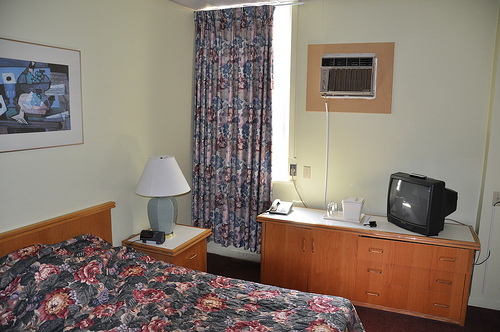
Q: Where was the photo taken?
A: It was taken at the hotel room.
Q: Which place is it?
A: It is a hotel room.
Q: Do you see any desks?
A: No, there are no desks.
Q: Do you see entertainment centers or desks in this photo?
A: No, there are no desks or entertainment centers.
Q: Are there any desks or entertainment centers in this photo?
A: No, there are no desks or entertainment centers.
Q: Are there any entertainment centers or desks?
A: No, there are no desks or entertainment centers.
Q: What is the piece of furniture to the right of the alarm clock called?
A: The piece of furniture is a dresser.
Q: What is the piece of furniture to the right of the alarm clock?
A: The piece of furniture is a dresser.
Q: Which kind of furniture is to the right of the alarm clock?
A: The piece of furniture is a dresser.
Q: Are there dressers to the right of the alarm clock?
A: Yes, there is a dresser to the right of the alarm clock.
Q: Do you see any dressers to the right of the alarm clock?
A: Yes, there is a dresser to the right of the alarm clock.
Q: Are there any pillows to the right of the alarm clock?
A: No, there is a dresser to the right of the alarm clock.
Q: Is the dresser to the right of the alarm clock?
A: Yes, the dresser is to the right of the alarm clock.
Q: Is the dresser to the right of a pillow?
A: No, the dresser is to the right of the alarm clock.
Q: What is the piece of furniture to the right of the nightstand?
A: The piece of furniture is a dresser.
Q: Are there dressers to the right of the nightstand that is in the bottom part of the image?
A: Yes, there is a dresser to the right of the nightstand.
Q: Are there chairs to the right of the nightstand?
A: No, there is a dresser to the right of the nightstand.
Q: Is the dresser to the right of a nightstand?
A: Yes, the dresser is to the right of a nightstand.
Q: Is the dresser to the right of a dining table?
A: No, the dresser is to the right of a nightstand.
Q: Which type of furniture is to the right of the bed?
A: The piece of furniture is a dresser.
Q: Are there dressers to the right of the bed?
A: Yes, there is a dresser to the right of the bed.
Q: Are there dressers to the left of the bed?
A: No, the dresser is to the right of the bed.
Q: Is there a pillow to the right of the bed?
A: No, there is a dresser to the right of the bed.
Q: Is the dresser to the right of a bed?
A: Yes, the dresser is to the right of a bed.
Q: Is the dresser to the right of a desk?
A: No, the dresser is to the right of a bed.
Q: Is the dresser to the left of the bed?
A: No, the dresser is to the right of the bed.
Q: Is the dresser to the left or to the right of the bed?
A: The dresser is to the right of the bed.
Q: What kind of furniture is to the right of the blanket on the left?
A: The piece of furniture is a dresser.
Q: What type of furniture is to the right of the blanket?
A: The piece of furniture is a dresser.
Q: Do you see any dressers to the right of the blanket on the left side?
A: Yes, there is a dresser to the right of the blanket.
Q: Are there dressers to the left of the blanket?
A: No, the dresser is to the right of the blanket.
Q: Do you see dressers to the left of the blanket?
A: No, the dresser is to the right of the blanket.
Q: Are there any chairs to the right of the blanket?
A: No, there is a dresser to the right of the blanket.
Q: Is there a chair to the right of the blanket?
A: No, there is a dresser to the right of the blanket.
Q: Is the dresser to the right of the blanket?
A: Yes, the dresser is to the right of the blanket.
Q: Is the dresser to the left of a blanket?
A: No, the dresser is to the right of a blanket.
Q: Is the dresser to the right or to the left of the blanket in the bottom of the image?
A: The dresser is to the right of the blanket.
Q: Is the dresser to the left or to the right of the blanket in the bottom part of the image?
A: The dresser is to the right of the blanket.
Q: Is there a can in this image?
A: No, there are no cans.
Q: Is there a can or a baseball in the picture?
A: No, there are no cans or baseballs.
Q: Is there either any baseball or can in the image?
A: No, there are no cans or baseballs.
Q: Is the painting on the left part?
A: Yes, the painting is on the left of the image.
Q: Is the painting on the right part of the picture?
A: No, the painting is on the left of the image.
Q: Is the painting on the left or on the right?
A: The painting is on the left of the image.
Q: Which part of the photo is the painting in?
A: The painting is on the left of the image.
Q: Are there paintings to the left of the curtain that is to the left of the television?
A: Yes, there is a painting to the left of the curtain.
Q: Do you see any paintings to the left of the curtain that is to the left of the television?
A: Yes, there is a painting to the left of the curtain.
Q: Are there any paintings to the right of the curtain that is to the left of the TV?
A: No, the painting is to the left of the curtain.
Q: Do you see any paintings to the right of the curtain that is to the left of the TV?
A: No, the painting is to the left of the curtain.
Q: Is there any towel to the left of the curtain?
A: No, there is a painting to the left of the curtain.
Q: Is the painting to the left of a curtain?
A: Yes, the painting is to the left of a curtain.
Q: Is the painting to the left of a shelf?
A: No, the painting is to the left of a curtain.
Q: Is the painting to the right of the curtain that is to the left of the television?
A: No, the painting is to the left of the curtain.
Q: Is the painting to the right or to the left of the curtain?
A: The painting is to the left of the curtain.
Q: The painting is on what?
A: The painting is on the wall.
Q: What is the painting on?
A: The painting is on the wall.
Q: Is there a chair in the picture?
A: No, there are no chairs.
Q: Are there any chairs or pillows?
A: No, there are no chairs or pillows.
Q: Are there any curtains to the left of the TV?
A: Yes, there is a curtain to the left of the TV.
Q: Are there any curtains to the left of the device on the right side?
A: Yes, there is a curtain to the left of the TV.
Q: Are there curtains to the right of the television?
A: No, the curtain is to the left of the television.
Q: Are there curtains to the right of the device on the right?
A: No, the curtain is to the left of the television.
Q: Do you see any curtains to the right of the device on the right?
A: No, the curtain is to the left of the television.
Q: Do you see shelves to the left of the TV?
A: No, there is a curtain to the left of the TV.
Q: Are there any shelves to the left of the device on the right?
A: No, there is a curtain to the left of the TV.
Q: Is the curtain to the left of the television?
A: Yes, the curtain is to the left of the television.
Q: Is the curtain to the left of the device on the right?
A: Yes, the curtain is to the left of the television.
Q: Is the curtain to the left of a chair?
A: No, the curtain is to the left of the television.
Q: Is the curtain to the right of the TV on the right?
A: No, the curtain is to the left of the television.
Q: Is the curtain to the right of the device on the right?
A: No, the curtain is to the left of the television.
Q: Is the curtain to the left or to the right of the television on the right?
A: The curtain is to the left of the television.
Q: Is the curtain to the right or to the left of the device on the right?
A: The curtain is to the left of the television.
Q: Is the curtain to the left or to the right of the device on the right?
A: The curtain is to the left of the television.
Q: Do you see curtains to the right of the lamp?
A: Yes, there is a curtain to the right of the lamp.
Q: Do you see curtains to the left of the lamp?
A: No, the curtain is to the right of the lamp.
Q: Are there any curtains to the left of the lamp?
A: No, the curtain is to the right of the lamp.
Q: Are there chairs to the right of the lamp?
A: No, there is a curtain to the right of the lamp.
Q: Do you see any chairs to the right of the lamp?
A: No, there is a curtain to the right of the lamp.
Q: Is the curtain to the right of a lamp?
A: Yes, the curtain is to the right of a lamp.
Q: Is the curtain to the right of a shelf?
A: No, the curtain is to the right of a lamp.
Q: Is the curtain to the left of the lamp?
A: No, the curtain is to the right of the lamp.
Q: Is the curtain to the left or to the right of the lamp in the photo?
A: The curtain is to the right of the lamp.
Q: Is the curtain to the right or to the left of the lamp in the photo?
A: The curtain is to the right of the lamp.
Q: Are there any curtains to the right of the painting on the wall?
A: Yes, there is a curtain to the right of the painting.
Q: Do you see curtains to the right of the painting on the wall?
A: Yes, there is a curtain to the right of the painting.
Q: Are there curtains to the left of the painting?
A: No, the curtain is to the right of the painting.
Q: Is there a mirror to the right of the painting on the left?
A: No, there is a curtain to the right of the painting.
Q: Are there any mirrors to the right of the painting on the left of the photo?
A: No, there is a curtain to the right of the painting.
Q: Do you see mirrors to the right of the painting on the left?
A: No, there is a curtain to the right of the painting.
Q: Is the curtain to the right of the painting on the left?
A: Yes, the curtain is to the right of the painting.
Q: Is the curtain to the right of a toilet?
A: No, the curtain is to the right of the painting.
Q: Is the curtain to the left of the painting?
A: No, the curtain is to the right of the painting.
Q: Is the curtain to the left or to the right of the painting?
A: The curtain is to the right of the painting.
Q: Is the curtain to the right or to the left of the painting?
A: The curtain is to the right of the painting.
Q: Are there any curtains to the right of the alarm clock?
A: Yes, there is a curtain to the right of the alarm clock.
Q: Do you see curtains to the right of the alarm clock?
A: Yes, there is a curtain to the right of the alarm clock.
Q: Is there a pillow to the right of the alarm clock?
A: No, there is a curtain to the right of the alarm clock.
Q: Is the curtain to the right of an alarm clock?
A: Yes, the curtain is to the right of an alarm clock.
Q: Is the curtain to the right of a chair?
A: No, the curtain is to the right of an alarm clock.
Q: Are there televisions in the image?
A: Yes, there is a television.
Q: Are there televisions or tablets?
A: Yes, there is a television.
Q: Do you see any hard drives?
A: No, there are no hard drives.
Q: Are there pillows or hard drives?
A: No, there are no hard drives or pillows.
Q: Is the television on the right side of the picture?
A: Yes, the television is on the right of the image.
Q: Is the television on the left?
A: No, the television is on the right of the image.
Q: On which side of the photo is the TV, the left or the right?
A: The TV is on the right of the image.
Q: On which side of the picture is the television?
A: The television is on the right of the image.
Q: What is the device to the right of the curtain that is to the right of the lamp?
A: The device is a television.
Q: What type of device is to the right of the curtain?
A: The device is a television.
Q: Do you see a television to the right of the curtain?
A: Yes, there is a television to the right of the curtain.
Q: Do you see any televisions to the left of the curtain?
A: No, the television is to the right of the curtain.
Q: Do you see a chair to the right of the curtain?
A: No, there is a television to the right of the curtain.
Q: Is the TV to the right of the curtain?
A: Yes, the TV is to the right of the curtain.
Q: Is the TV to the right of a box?
A: No, the TV is to the right of the curtain.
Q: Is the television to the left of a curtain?
A: No, the television is to the right of a curtain.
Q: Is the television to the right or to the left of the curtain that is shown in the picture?
A: The television is to the right of the curtain.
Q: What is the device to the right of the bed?
A: The device is a television.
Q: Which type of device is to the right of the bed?
A: The device is a television.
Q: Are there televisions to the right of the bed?
A: Yes, there is a television to the right of the bed.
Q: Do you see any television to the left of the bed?
A: No, the television is to the right of the bed.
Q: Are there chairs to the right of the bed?
A: No, there is a television to the right of the bed.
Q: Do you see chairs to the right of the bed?
A: No, there is a television to the right of the bed.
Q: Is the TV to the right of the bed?
A: Yes, the TV is to the right of the bed.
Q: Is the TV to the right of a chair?
A: No, the TV is to the right of the bed.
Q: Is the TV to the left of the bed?
A: No, the TV is to the right of the bed.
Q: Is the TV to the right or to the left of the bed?
A: The TV is to the right of the bed.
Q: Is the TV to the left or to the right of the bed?
A: The TV is to the right of the bed.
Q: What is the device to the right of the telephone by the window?
A: The device is a television.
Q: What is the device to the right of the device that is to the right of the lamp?
A: The device is a television.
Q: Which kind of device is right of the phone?
A: The device is a television.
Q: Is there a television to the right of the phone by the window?
A: Yes, there is a television to the right of the phone.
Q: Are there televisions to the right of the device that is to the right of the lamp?
A: Yes, there is a television to the right of the phone.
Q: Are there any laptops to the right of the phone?
A: No, there is a television to the right of the phone.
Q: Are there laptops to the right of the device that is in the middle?
A: No, there is a television to the right of the phone.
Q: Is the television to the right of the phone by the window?
A: Yes, the television is to the right of the telephone.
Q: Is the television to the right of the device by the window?
A: Yes, the television is to the right of the telephone.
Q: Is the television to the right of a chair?
A: No, the television is to the right of the telephone.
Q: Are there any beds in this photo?
A: Yes, there is a bed.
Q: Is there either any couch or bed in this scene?
A: Yes, there is a bed.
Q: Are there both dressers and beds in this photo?
A: Yes, there are both a bed and a dresser.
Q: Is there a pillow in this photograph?
A: No, there are no pillows.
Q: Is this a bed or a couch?
A: This is a bed.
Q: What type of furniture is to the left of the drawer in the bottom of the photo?
A: The piece of furniture is a bed.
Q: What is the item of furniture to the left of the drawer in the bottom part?
A: The piece of furniture is a bed.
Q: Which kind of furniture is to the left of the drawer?
A: The piece of furniture is a bed.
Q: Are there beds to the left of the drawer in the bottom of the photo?
A: Yes, there is a bed to the left of the drawer.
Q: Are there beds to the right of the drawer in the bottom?
A: No, the bed is to the left of the drawer.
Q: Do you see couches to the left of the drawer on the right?
A: No, there is a bed to the left of the drawer.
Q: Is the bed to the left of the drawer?
A: Yes, the bed is to the left of the drawer.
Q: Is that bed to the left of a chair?
A: No, the bed is to the left of the drawer.